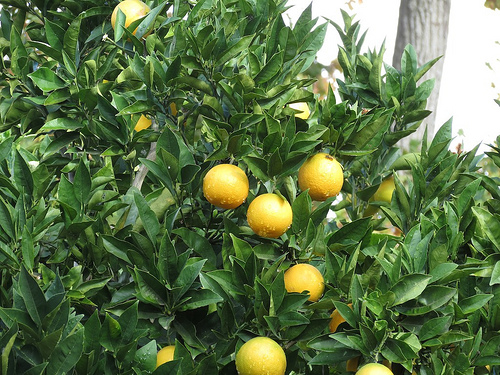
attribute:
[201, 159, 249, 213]
lemon — yellow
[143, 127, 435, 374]
lemons — yellow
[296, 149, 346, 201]
lemon — yellow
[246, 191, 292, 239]
lemon — yellow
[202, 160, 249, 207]
lemon — yellow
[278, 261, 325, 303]
lemon — yellow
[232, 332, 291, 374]
lemon — yellow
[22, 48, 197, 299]
leaves — green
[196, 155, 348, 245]
lemon — green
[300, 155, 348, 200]
lemon — spherical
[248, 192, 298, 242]
lemon — spherical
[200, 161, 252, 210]
lemon — spherical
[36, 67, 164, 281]
leaves — green